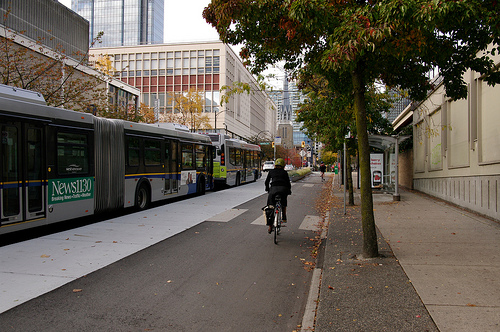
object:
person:
[261, 154, 294, 234]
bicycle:
[261, 200, 288, 246]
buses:
[196, 134, 259, 193]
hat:
[273, 156, 286, 171]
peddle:
[279, 223, 286, 226]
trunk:
[347, 68, 380, 259]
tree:
[216, 1, 497, 260]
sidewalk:
[18, 215, 176, 277]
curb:
[36, 225, 88, 232]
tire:
[128, 174, 156, 212]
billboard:
[48, 172, 96, 203]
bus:
[2, 87, 108, 224]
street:
[2, 48, 242, 270]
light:
[250, 133, 264, 152]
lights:
[250, 127, 290, 148]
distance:
[222, 86, 349, 153]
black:
[270, 174, 282, 195]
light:
[218, 153, 225, 159]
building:
[0, 0, 150, 114]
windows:
[141, 60, 152, 70]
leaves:
[304, 265, 319, 273]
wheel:
[133, 178, 155, 213]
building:
[87, 40, 277, 147]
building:
[276, 55, 309, 125]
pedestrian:
[320, 158, 331, 189]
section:
[164, 1, 213, 41]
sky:
[167, 3, 201, 38]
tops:
[213, 1, 482, 39]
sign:
[369, 150, 383, 189]